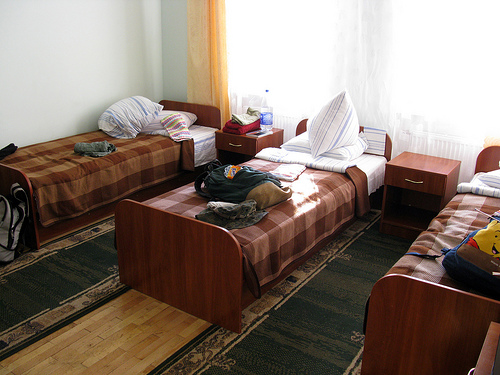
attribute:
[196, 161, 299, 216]
bag — black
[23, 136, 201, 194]
blanket — brown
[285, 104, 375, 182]
pillows — stripes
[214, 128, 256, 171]
side table — brown, wooden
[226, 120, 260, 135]
towel — red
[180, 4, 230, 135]
curtain — yellow, peach